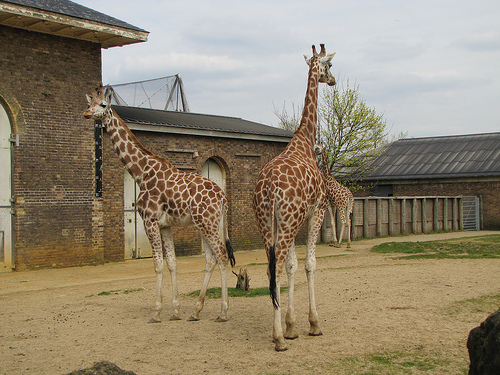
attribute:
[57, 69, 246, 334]
giraffe — baby, young, mom, long, 3, brown, looking, standing, three, inside, observing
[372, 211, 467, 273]
grass — patch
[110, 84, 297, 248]
building — old, brick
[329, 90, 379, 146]
tree — young, small, large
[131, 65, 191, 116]
fence — flimsy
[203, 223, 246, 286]
tail — mom, black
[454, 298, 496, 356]
rock — big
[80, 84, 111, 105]
horn — small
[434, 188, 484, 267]
gate — short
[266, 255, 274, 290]
hair — black, back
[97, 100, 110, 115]
eye — small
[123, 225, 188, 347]
leg — bottom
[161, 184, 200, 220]
spot — brown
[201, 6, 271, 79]
day — cloudy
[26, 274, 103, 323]
ground — dirty